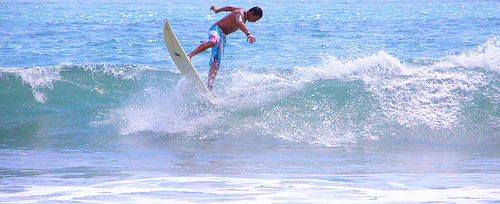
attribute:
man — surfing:
[190, 7, 262, 87]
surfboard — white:
[160, 24, 207, 111]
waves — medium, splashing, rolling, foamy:
[4, 56, 498, 152]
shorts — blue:
[203, 28, 226, 66]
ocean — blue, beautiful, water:
[3, 4, 495, 201]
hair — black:
[249, 6, 263, 18]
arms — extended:
[209, 3, 253, 45]